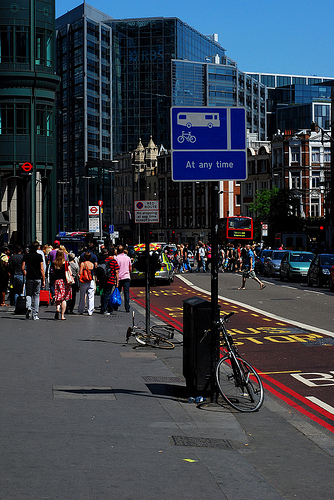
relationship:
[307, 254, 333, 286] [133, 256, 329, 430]
parked cars on road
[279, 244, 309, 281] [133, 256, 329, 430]
parked cars on road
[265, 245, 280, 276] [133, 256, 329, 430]
parked cars on road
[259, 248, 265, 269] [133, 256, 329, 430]
parked cars on road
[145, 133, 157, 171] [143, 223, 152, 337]
light on black pole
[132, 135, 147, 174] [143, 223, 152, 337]
light on black pole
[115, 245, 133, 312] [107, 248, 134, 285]
man wearing shirt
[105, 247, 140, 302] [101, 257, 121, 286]
man wearing shirt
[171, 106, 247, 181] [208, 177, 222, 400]
blue sign on street pole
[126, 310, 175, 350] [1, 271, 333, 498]
bicycle laying on ground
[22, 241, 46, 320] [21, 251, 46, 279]
person wearing shirt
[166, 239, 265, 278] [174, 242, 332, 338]
people in street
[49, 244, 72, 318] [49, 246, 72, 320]
woman wearing skirt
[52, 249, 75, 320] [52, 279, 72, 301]
woman wearing skirt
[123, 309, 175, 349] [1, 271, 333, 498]
bicycle on ground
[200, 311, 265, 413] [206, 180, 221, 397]
bicycle leaning against pole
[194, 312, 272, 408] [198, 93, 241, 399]
bicycle leaning against pole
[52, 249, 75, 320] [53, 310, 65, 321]
woman wearing shoes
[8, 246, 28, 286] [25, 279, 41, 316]
man wearing jeans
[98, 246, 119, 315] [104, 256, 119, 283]
person wearing shirt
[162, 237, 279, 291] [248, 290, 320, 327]
people crossing street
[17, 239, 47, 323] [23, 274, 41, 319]
person wearing jeans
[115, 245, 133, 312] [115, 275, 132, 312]
man wearing jeans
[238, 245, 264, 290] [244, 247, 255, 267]
people wearing blue shirt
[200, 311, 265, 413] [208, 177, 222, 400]
bicycle parked on street pole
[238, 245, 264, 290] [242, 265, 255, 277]
people wearing shorts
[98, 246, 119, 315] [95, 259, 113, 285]
person carrying back pack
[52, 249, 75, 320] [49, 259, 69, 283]
woman wearing blouse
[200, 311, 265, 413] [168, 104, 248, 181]
bicycle parked near sign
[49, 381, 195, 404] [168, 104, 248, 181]
shadow of sign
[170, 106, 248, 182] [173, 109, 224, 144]
blue sign for buses/bikes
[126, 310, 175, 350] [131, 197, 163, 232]
bicycle near sign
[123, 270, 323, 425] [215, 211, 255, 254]
strip for bus